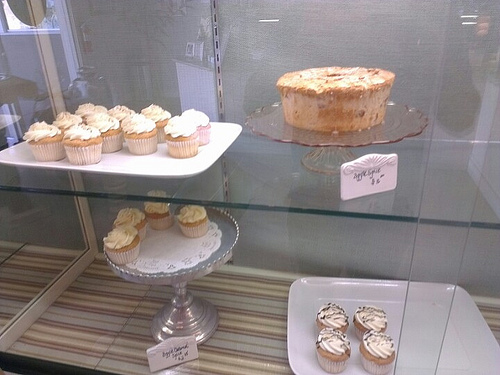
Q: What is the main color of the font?
A: Black.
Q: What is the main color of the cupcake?
A: Brown.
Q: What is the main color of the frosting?
A: White.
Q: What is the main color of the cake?
A: Brown.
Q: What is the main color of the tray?
A: Gray.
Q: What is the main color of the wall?
A: White.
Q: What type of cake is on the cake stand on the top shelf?
A: Angel food cake.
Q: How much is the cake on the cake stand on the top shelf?
A: $5.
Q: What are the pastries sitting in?
A: Glass case.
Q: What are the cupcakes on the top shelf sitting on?
A: White plate.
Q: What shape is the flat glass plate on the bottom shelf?
A: Square.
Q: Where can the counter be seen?
A: In the reflection.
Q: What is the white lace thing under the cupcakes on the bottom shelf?
A: Doily.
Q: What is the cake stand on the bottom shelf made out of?
A: Metal.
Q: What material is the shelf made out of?
A: Glass.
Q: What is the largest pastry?
A: Cake.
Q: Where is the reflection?
A: Glass display.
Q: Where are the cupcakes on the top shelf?
A: White plate.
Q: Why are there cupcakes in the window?
A: On display.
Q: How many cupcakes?
A: 18.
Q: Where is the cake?
A: In the window.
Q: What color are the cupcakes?
A: White.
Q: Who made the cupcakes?
A: The baker.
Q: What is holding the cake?
A: A cake holder.